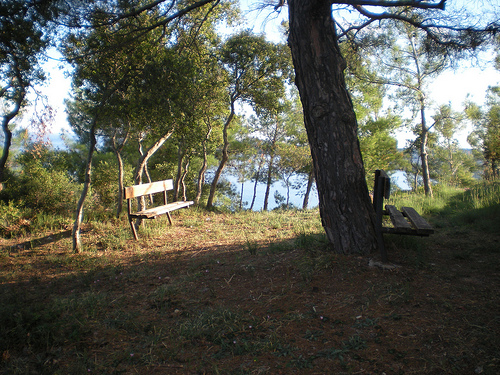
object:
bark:
[315, 49, 341, 168]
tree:
[279, 0, 389, 262]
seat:
[121, 177, 195, 220]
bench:
[122, 176, 196, 241]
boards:
[127, 201, 197, 223]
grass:
[397, 175, 467, 206]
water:
[290, 187, 302, 200]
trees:
[59, 26, 182, 252]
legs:
[131, 216, 141, 233]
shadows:
[0, 212, 486, 366]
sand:
[176, 210, 302, 235]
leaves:
[61, 33, 103, 142]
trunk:
[413, 37, 434, 200]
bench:
[368, 167, 439, 261]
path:
[185, 254, 329, 343]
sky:
[45, 57, 70, 98]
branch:
[337, 1, 499, 51]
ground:
[0, 188, 499, 373]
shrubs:
[15, 141, 126, 226]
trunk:
[282, 0, 382, 262]